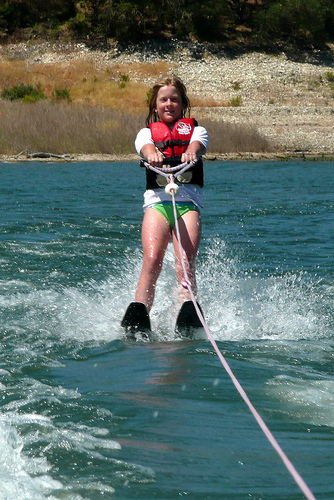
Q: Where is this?
A: This is at the lake.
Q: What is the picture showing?
A: It is showing a lake.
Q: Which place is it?
A: It is a lake.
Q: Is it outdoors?
A: Yes, it is outdoors.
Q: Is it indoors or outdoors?
A: It is outdoors.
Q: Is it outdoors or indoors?
A: It is outdoors.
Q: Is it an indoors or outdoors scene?
A: It is outdoors.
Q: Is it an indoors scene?
A: No, it is outdoors.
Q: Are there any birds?
A: No, there are no birds.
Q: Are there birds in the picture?
A: No, there are no birds.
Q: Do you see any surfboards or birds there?
A: No, there are no birds or surfboards.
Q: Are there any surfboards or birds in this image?
A: No, there are no birds or surfboards.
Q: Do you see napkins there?
A: No, there are no napkins.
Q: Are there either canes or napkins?
A: No, there are no napkins or canes.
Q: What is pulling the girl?
A: The rope is pulling the girl.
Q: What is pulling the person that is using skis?
A: The rope is pulling the girl.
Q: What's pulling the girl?
A: The rope is pulling the girl.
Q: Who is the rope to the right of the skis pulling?
A: The rope is pulling the girl.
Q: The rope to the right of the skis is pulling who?
A: The rope is pulling the girl.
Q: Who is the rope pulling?
A: The rope is pulling the girl.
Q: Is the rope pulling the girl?
A: Yes, the rope is pulling the girl.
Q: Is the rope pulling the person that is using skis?
A: Yes, the rope is pulling the girl.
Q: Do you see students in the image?
A: No, there are no students.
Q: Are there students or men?
A: No, there are no students or men.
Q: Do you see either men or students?
A: No, there are no students or men.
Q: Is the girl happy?
A: Yes, the girl is happy.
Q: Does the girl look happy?
A: Yes, the girl is happy.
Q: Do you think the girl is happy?
A: Yes, the girl is happy.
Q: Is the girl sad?
A: No, the girl is happy.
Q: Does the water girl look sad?
A: No, the girl is happy.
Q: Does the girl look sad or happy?
A: The girl is happy.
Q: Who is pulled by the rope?
A: The girl is pulled by the rope.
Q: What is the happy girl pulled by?
A: The girl is pulled by the rope.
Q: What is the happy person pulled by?
A: The girl is pulled by the rope.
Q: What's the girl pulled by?
A: The girl is pulled by the rope.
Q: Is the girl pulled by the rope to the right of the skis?
A: Yes, the girl is pulled by the rope.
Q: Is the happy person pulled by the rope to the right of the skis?
A: Yes, the girl is pulled by the rope.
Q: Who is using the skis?
A: The girl is using the skis.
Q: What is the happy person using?
A: The girl is using skis.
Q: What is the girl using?
A: The girl is using skis.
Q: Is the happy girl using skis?
A: Yes, the girl is using skis.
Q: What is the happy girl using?
A: The girl is using skis.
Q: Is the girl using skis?
A: Yes, the girl is using skis.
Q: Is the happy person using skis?
A: Yes, the girl is using skis.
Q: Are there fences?
A: No, there are no fences.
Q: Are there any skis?
A: Yes, there are skis.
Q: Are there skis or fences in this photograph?
A: Yes, there are skis.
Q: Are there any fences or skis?
A: Yes, there are skis.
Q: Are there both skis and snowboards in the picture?
A: No, there are skis but no snowboards.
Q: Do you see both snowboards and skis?
A: No, there are skis but no snowboards.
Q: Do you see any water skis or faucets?
A: Yes, there are water skis.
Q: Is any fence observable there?
A: No, there are no fences.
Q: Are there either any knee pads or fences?
A: No, there are no fences or knee pads.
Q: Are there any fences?
A: No, there are no fences.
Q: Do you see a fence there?
A: No, there are no fences.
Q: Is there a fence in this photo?
A: No, there are no fences.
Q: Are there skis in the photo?
A: Yes, there are skis.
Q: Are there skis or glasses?
A: Yes, there are skis.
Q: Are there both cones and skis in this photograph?
A: No, there are skis but no cones.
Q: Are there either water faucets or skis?
A: Yes, there are water skis.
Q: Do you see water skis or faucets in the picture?
A: Yes, there are water skis.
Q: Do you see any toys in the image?
A: No, there are no toys.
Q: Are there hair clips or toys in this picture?
A: No, there are no toys or hair clips.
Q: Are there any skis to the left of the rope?
A: Yes, there are skis to the left of the rope.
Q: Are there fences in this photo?
A: No, there are no fences.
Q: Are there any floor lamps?
A: No, there are no floor lamps.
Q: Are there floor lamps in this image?
A: No, there are no floor lamps.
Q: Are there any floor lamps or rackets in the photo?
A: No, there are no floor lamps or rackets.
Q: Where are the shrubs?
A: The shrubs are on the shore.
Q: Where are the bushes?
A: The shrubs are on the shore.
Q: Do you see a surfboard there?
A: No, there are no surfboards.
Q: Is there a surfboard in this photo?
A: No, there are no surfboards.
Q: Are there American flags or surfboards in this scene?
A: No, there are no surfboards or American flags.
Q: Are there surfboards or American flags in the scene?
A: No, there are no surfboards or American flags.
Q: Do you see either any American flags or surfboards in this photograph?
A: No, there are no surfboards or American flags.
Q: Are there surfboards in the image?
A: No, there are no surfboards.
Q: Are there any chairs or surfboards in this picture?
A: No, there are no surfboards or chairs.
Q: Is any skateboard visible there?
A: No, there are no skateboards.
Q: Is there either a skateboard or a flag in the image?
A: No, there are no skateboards or flags.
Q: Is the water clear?
A: Yes, the water is clear.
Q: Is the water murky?
A: No, the water is clear.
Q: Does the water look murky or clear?
A: The water is clear.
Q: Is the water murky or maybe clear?
A: The water is clear.